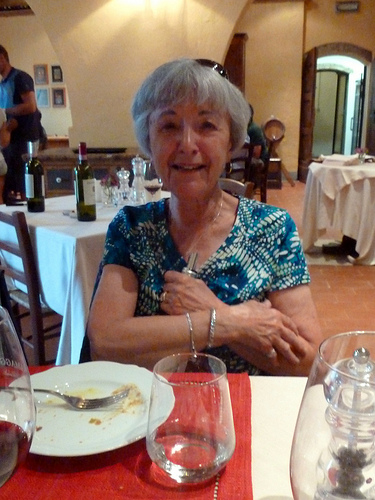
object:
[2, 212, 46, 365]
chair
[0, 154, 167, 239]
table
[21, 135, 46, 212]
bottle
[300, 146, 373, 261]
table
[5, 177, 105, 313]
table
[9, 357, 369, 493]
table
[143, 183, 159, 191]
wine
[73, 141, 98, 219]
wine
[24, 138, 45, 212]
wine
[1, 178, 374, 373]
floor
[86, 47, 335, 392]
woman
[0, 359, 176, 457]
plate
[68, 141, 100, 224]
bottle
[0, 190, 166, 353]
table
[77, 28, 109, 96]
wall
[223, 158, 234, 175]
earrings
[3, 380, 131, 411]
fork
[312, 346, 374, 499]
pepper cracker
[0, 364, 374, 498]
table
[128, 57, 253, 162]
gray hair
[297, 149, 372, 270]
table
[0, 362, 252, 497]
place mat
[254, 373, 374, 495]
table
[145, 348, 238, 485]
cup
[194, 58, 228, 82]
sunglasses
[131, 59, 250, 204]
head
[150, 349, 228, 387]
edge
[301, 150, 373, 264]
table cloths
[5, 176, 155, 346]
table cloths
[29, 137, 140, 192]
table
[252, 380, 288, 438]
tabled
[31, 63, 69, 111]
pictures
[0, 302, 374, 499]
glass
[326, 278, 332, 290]
light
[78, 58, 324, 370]
woman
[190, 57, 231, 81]
sunglasses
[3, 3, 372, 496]
camera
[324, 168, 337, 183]
part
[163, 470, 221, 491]
bottom